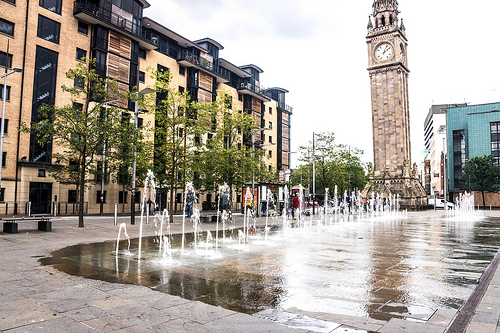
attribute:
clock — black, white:
[373, 42, 392, 60]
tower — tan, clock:
[360, 0, 427, 206]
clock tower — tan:
[366, 6, 413, 181]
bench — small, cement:
[7, 201, 54, 243]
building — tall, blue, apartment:
[423, 102, 499, 179]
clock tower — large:
[364, 2, 429, 204]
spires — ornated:
[364, 12, 404, 33]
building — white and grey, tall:
[425, 101, 462, 196]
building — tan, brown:
[2, 2, 290, 217]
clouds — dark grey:
[141, 0, 498, 180]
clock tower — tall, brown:
[364, 4, 419, 178]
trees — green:
[301, 130, 371, 193]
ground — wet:
[3, 215, 495, 332]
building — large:
[2, 4, 287, 186]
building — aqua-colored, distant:
[439, 108, 494, 195]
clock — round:
[374, 42, 390, 59]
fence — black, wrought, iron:
[1, 201, 87, 214]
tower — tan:
[345, 1, 424, 206]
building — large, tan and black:
[3, 11, 296, 231]